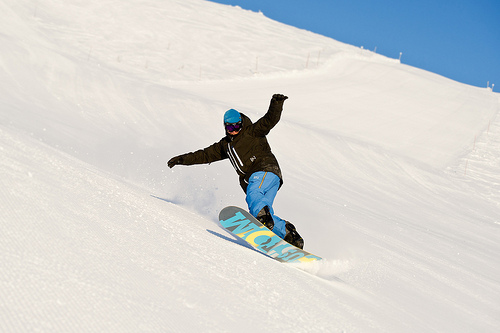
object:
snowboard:
[216, 204, 322, 264]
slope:
[0, 0, 499, 332]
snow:
[0, 0, 499, 332]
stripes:
[230, 145, 244, 166]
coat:
[174, 102, 284, 195]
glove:
[270, 93, 288, 109]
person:
[166, 93, 305, 250]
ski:
[218, 205, 324, 264]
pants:
[241, 171, 288, 240]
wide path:
[156, 48, 500, 173]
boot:
[281, 218, 305, 250]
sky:
[213, 0, 500, 97]